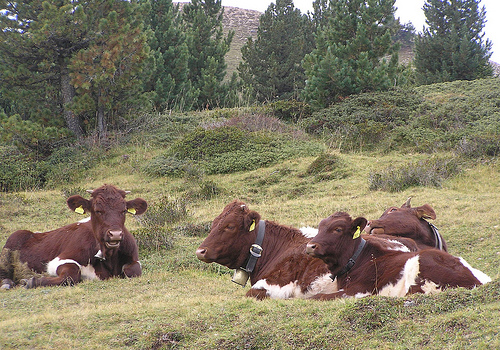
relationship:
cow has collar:
[197, 201, 420, 302] [238, 216, 267, 276]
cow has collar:
[310, 210, 489, 302] [331, 235, 365, 278]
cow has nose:
[2, 185, 147, 291] [108, 229, 122, 239]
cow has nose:
[364, 194, 446, 252] [365, 221, 373, 231]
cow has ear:
[197, 201, 420, 302] [242, 210, 261, 230]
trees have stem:
[6, 2, 235, 105] [17, 131, 134, 142]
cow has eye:
[310, 210, 489, 302] [333, 227, 343, 235]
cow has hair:
[2, 185, 147, 291] [48, 257, 106, 283]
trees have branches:
[6, 2, 235, 105] [9, 32, 94, 65]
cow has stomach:
[2, 185, 147, 291] [9, 251, 57, 280]